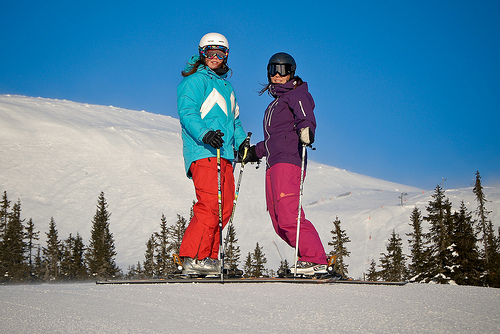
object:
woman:
[178, 32, 243, 273]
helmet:
[197, 32, 229, 69]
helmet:
[267, 52, 297, 84]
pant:
[178, 157, 235, 259]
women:
[252, 51, 328, 279]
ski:
[251, 278, 405, 285]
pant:
[265, 164, 330, 264]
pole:
[215, 140, 225, 282]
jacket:
[253, 83, 317, 169]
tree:
[85, 191, 119, 279]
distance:
[0, 178, 178, 275]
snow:
[49, 112, 158, 198]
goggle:
[199, 46, 229, 60]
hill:
[0, 93, 425, 227]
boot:
[182, 255, 231, 279]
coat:
[176, 63, 246, 178]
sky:
[0, 0, 500, 106]